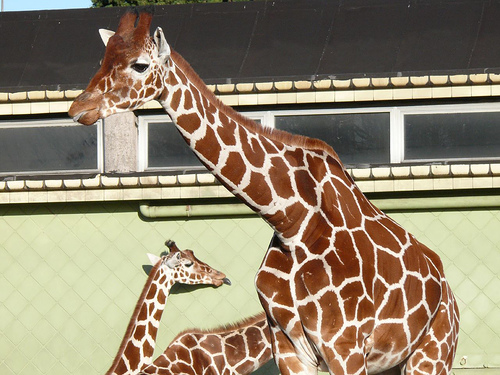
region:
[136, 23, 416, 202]
this is a giraffe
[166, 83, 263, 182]
this is the neck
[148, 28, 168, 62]
this is the ear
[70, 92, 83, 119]
this is the nose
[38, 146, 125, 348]
this is a wall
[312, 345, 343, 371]
this is the leg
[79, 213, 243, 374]
This is a giraffe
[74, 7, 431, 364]
This is a giraffe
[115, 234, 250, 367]
This is a giraffe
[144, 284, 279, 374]
This is a giraffe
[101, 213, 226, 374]
This is a giraffe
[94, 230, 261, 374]
This is a giraffe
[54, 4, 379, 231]
This is a giraffe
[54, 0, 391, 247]
This is a giraffe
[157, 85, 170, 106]
brown spot on giraffe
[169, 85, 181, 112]
brown spot on giraffe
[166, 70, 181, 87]
brown spot on giraffe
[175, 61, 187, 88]
brown spot on giraffe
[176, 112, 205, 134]
brown spot on giraffe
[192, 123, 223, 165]
brown spot on giraffe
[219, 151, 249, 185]
brown spot on giraffe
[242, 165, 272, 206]
brown spot on giraffe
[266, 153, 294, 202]
brown spot on giraffe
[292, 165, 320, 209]
brown spot on giraffe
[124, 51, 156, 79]
the eye of a giraffe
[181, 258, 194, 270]
the eye of a giraffe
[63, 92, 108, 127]
the mouth of a giraffe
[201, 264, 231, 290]
the mouth of a giraffe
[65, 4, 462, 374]
a giraffe in a fenced in area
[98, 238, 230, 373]
a giraffe in a fenced in area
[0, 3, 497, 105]
a black roof on a building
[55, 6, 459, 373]
three giraffes close together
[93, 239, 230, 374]
a giraffe with it's tongue out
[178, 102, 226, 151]
neck of the giraffe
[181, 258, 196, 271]
the eye of the giraffe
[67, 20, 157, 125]
the giraffes head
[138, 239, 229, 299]
a small giraffe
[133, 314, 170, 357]
the neck of the giraffe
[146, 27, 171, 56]
ear of the giraffe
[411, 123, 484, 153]
windows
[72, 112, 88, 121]
tongu of the giraffe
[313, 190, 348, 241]
a spot on the giraffe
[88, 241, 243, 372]
baby giraffe below parent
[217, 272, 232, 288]
gray giraffe tongue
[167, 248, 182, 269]
white giraffe ear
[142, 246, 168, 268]
white giraffe ear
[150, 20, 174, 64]
white giraffe ear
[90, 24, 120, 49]
white giraffe ear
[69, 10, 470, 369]
large adult giraffe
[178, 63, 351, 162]
brown fur on giraffe neck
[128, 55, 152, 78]
round black giraffe eye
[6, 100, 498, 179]
row of rectangular windows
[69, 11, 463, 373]
large spotted brown giraffe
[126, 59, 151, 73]
large almond shaped black eye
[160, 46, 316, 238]
long spotted grown neck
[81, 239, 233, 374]
tall giraffe sticking out tongue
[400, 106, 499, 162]
large rectangular square window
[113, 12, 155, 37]
short brown furry horns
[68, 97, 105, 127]
large brown giraffe mouth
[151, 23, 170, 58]
small white furry ear